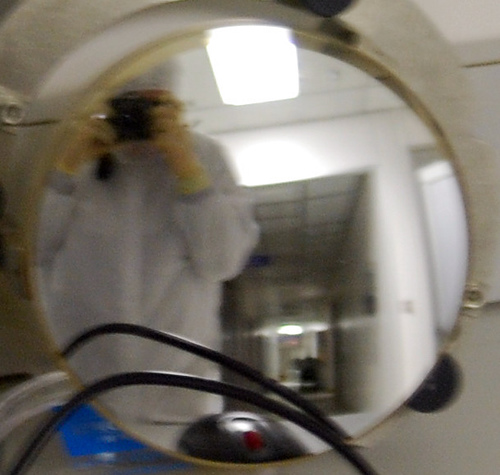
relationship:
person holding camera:
[33, 55, 262, 425] [95, 92, 166, 147]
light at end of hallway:
[279, 316, 310, 341] [216, 169, 390, 434]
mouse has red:
[171, 400, 313, 462] [238, 424, 266, 450]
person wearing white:
[33, 55, 262, 425] [63, 137, 233, 417]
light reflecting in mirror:
[279, 316, 310, 341] [26, 25, 475, 467]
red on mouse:
[238, 424, 266, 450] [171, 400, 313, 462]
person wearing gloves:
[33, 55, 262, 425] [59, 99, 197, 206]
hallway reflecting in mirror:
[216, 169, 390, 434] [26, 25, 475, 467]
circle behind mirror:
[400, 349, 470, 415] [26, 25, 475, 467]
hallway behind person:
[216, 169, 390, 434] [33, 55, 262, 425]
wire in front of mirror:
[0, 369, 373, 474] [26, 25, 475, 467]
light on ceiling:
[279, 316, 310, 341] [247, 195, 345, 317]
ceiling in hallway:
[247, 195, 345, 317] [216, 169, 390, 434]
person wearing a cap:
[33, 55, 262, 425] [114, 56, 190, 100]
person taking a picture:
[33, 55, 262, 425] [95, 92, 166, 147]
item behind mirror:
[54, 400, 156, 463] [26, 25, 475, 467]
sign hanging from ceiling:
[242, 247, 276, 272] [247, 195, 345, 317]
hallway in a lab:
[216, 169, 390, 434] [0, 1, 499, 474]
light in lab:
[279, 316, 310, 341] [0, 1, 499, 474]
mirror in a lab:
[26, 25, 475, 467] [0, 1, 499, 474]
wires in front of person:
[0, 318, 383, 474] [33, 55, 262, 425]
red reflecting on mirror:
[238, 424, 266, 450] [26, 25, 475, 467]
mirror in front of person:
[26, 25, 475, 467] [33, 55, 262, 425]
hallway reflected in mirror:
[216, 169, 390, 434] [26, 25, 475, 467]